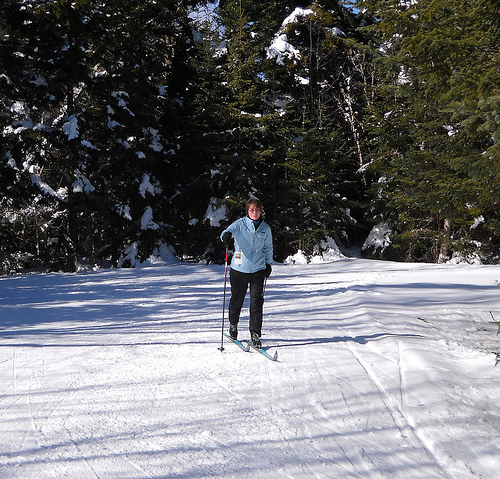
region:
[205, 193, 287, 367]
Skier posing for photo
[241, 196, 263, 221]
Woman wearing eye glasses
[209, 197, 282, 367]
Woman skier on snow trail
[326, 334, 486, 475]
Ski and vehicle tracks in snow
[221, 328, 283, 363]
Boots strapped into skies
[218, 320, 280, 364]
Ski traversing snow trail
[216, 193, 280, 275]
Woman wearing glasses and blue jacket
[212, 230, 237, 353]
Right hand holding ski pole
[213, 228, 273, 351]
Skier holding two ski poles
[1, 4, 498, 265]
Snow covered fir trees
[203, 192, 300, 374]
A woman is skiing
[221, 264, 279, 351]
Woman is wearing black pants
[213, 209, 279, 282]
Woman is wearing a blue coat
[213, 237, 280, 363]
Woman is holding ski poles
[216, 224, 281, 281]
Woman is wearing black gloves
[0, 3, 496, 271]
Pine trees in the background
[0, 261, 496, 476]
Snow is covering the ground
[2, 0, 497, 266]
Snow is covering the trees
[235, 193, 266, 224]
Woman has dark brown colored hair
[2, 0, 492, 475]
Photo was taken in the daytime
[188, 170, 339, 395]
this is a woman on skis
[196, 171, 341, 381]
she is skiing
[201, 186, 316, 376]
the woman is skiing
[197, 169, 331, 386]
she is skiing in the snow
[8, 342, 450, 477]
there are ski tracks in the snow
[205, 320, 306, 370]
her skis are narrow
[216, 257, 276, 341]
her pants are black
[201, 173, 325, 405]
she is wearing a light blue jacket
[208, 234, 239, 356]
the ski pole is red and black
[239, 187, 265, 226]
she is wearing glasses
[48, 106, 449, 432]
A person is up in the mountains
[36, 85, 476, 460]
A person is doing some snow skiing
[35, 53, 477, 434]
A person is wearing a warm jacket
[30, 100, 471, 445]
A person is using snow skis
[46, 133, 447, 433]
A person is casting a shadow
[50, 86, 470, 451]
A person is wearing nice ski boots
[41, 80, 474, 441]
A person is close to a ski lodge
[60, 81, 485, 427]
A person is looking for her friends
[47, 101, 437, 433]
A person is out in the daytime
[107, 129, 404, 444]
A person is enjoying their day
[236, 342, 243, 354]
part of a skate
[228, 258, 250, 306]
part of a jacket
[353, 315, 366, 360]
part of a hill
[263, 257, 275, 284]
part of a glove